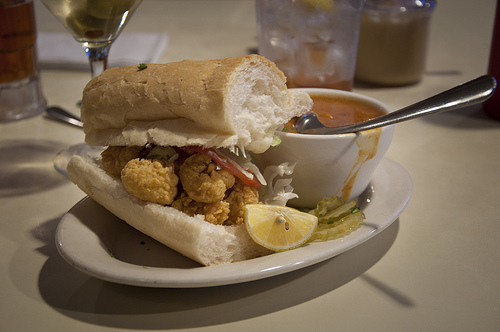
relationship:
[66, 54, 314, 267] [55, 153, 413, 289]
sandwich on plate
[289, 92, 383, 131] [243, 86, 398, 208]
soup in bowl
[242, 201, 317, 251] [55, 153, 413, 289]
lemon on plate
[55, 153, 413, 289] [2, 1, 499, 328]
plate on table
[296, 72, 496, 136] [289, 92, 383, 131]
spoon in soup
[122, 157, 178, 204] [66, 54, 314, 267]
shrimp on sandwich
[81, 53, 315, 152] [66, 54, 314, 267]
bread on sandwich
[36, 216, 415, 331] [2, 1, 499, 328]
shadow on table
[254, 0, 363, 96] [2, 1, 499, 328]
cup on table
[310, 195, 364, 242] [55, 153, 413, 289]
pickle on plate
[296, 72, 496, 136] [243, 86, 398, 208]
spoon in bowl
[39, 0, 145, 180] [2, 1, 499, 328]
glass on table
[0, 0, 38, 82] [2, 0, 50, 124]
liquid in cup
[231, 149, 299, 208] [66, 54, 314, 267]
lettuce on sandwich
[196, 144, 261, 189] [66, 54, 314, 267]
tomato on sandwich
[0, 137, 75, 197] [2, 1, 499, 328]
shadow on table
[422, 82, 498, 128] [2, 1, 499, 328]
shadow on table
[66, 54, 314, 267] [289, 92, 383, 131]
sandwich next to soup